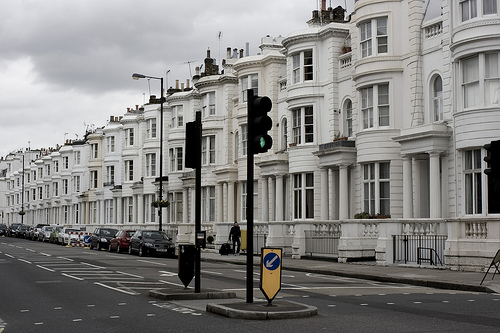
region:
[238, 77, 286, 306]
traffic signal on a pole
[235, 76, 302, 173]
traffic light showing green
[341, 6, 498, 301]
white buildings with windows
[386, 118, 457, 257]
pillars at an entry way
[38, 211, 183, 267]
cars parked along a street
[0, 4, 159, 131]
clouds in the sky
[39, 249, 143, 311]
white lines on the street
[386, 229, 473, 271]
black metal railing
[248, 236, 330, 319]
a yellow and blue sign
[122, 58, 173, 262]
a tall street lamp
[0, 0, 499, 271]
a ling section of row houses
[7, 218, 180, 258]
cars parked along the road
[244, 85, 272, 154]
a green traffic light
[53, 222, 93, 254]
orange and white striped road barricades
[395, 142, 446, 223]
entryway smooth round columns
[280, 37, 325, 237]
bowed sections on each unit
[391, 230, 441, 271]
wrought iron gates and steps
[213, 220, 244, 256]
man wheels luggage down the street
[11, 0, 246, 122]
dark grey cloudy sky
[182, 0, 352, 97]
Chimney and exhaust pipes on rooftops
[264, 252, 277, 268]
White arrow on blue circle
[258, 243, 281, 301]
Yellow traffic sign next to black traffic light pole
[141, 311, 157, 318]
Small white dash on road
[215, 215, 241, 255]
Man hauling black suitcase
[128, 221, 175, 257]
Black car parked in front of red car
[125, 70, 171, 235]
Tall light post next to red car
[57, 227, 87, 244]
White car parked in front of green car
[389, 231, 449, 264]
Black metal gate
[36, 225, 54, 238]
Silver car parked behind green car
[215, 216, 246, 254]
Man wearing jacket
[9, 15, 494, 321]
An urban street scene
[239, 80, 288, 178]
The traffic light is green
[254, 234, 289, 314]
This is a direction sign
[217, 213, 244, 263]
A person is walking on the sidewalk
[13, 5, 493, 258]
A row of buildings are along the street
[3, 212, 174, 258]
Cars are parked in front of the buildings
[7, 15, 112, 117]
The sky is cloudy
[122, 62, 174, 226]
This is a street lamp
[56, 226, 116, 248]
Saw horses are in between the parked cars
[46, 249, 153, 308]
Lines are painted on the asphalt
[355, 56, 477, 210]
the building is white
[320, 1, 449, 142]
the building is white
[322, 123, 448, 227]
the building is white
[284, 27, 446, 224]
the building is white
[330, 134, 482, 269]
the building is white